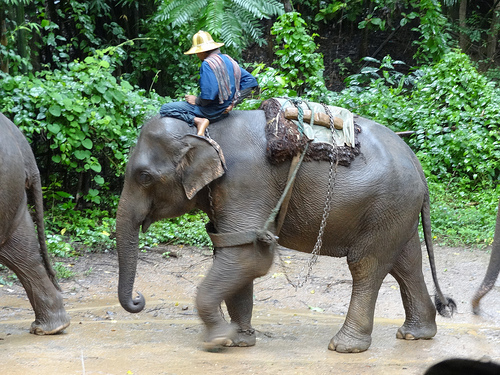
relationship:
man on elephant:
[160, 22, 258, 139] [114, 108, 460, 354]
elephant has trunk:
[114, 108, 460, 354] [106, 192, 150, 315]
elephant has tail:
[114, 108, 460, 354] [421, 175, 457, 322]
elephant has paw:
[114, 108, 460, 354] [199, 322, 245, 353]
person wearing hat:
[160, 22, 258, 139] [176, 29, 225, 54]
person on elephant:
[160, 22, 258, 139] [114, 108, 460, 354]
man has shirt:
[160, 22, 258, 139] [192, 52, 255, 115]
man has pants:
[160, 22, 258, 139] [154, 104, 227, 125]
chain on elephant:
[275, 102, 337, 286] [114, 108, 460, 354]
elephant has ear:
[114, 108, 460, 354] [172, 133, 227, 203]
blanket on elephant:
[261, 91, 360, 165] [114, 108, 460, 354]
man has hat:
[160, 22, 258, 139] [176, 29, 225, 54]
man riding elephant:
[160, 22, 258, 139] [114, 108, 460, 354]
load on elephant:
[261, 91, 360, 165] [114, 108, 460, 354]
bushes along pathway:
[3, 2, 496, 250] [4, 242, 498, 372]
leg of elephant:
[5, 204, 72, 334] [1, 113, 73, 335]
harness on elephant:
[205, 153, 305, 257] [114, 108, 460, 354]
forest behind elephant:
[3, 2, 496, 250] [114, 108, 460, 354]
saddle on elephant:
[261, 91, 360, 165] [114, 108, 460, 354]